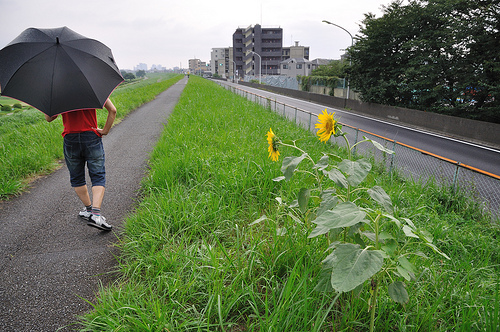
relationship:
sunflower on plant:
[315, 109, 338, 142] [247, 108, 449, 329]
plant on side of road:
[247, 108, 449, 329] [207, 76, 499, 228]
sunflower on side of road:
[264, 128, 282, 161] [207, 76, 499, 228]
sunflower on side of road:
[315, 109, 338, 142] [207, 76, 499, 228]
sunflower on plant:
[264, 128, 282, 161] [247, 108, 449, 329]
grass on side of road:
[1, 73, 498, 328] [207, 76, 499, 228]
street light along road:
[247, 49, 264, 84] [207, 76, 499, 228]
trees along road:
[309, 0, 499, 124] [207, 76, 499, 228]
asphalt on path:
[2, 74, 192, 330] [1, 74, 190, 330]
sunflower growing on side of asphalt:
[264, 128, 282, 161] [2, 74, 192, 330]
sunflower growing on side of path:
[264, 128, 282, 161] [1, 74, 190, 330]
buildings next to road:
[188, 24, 349, 87] [207, 76, 499, 228]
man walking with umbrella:
[40, 45, 116, 235] [0, 24, 124, 118]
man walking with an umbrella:
[40, 45, 116, 235] [0, 24, 124, 118]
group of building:
[198, 19, 315, 80] [200, 15, 320, 85]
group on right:
[198, 19, 315, 80] [203, 23, 456, 186]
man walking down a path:
[40, 45, 116, 235] [44, 74, 184, 285]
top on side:
[352, 13, 480, 93] [301, 19, 416, 179]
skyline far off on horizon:
[128, 60, 182, 76] [126, 18, 420, 68]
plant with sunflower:
[265, 101, 451, 321] [264, 128, 282, 161]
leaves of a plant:
[244, 167, 475, 317] [265, 101, 451, 321]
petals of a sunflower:
[320, 137, 330, 144] [315, 109, 338, 142]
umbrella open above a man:
[11, 23, 131, 116] [40, 45, 116, 235]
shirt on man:
[60, 115, 101, 131] [40, 45, 116, 235]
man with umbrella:
[40, 45, 116, 235] [14, 22, 127, 110]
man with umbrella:
[40, 45, 116, 235] [13, 24, 125, 121]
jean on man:
[58, 131, 106, 189] [40, 45, 116, 235]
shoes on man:
[77, 205, 116, 232] [40, 45, 116, 235]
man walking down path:
[40, 45, 116, 235] [15, 71, 181, 302]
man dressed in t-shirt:
[40, 45, 116, 235] [54, 112, 103, 135]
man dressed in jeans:
[40, 45, 116, 235] [63, 133, 109, 184]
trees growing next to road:
[373, 0, 499, 113] [207, 76, 499, 228]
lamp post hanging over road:
[323, 19, 353, 99] [207, 76, 499, 228]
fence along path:
[196, 71, 499, 231] [1, 74, 190, 330]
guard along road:
[204, 73, 499, 150] [207, 76, 499, 228]